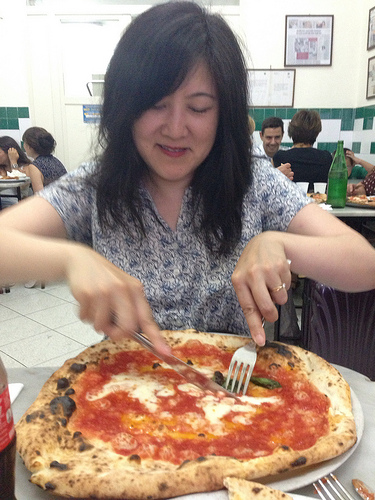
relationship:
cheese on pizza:
[91, 362, 280, 426] [15, 328, 363, 495]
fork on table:
[224, 258, 293, 395] [10, 343, 370, 495]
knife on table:
[352, 477, 373, 498] [14, 362, 373, 498]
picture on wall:
[283, 13, 335, 67] [249, 0, 373, 150]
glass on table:
[322, 135, 351, 208] [10, 249, 373, 478]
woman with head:
[0, 0, 371, 354] [101, 1, 249, 183]